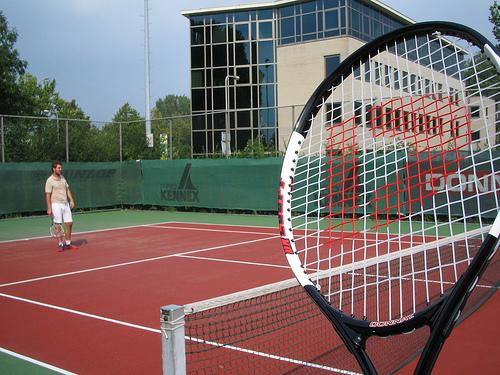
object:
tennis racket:
[278, 21, 500, 375]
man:
[44, 161, 79, 252]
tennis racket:
[49, 213, 65, 239]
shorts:
[51, 203, 73, 224]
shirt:
[45, 174, 70, 203]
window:
[213, 44, 228, 66]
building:
[191, 8, 474, 142]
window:
[237, 111, 250, 128]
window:
[278, 18, 294, 38]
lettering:
[422, 169, 499, 196]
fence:
[145, 161, 280, 212]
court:
[0, 225, 223, 295]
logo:
[159, 162, 201, 203]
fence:
[10, 116, 174, 161]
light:
[228, 75, 239, 81]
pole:
[224, 77, 231, 158]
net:
[192, 313, 312, 374]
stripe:
[173, 252, 279, 283]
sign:
[160, 133, 173, 160]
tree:
[149, 93, 192, 160]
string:
[305, 184, 309, 206]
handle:
[343, 341, 446, 374]